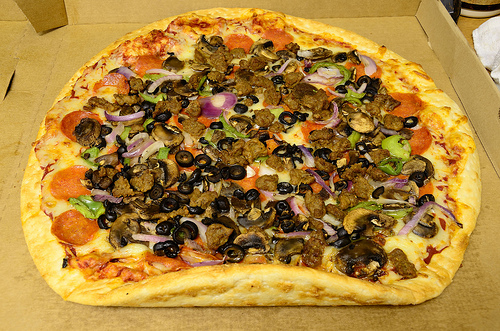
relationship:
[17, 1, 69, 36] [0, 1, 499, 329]
part of box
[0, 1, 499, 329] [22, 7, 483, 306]
box containing pizza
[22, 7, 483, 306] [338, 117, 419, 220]
pizza has toppings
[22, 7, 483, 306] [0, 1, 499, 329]
pizza in box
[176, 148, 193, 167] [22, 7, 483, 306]
olive on pizza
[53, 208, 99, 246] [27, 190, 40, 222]
pepperoni by edge